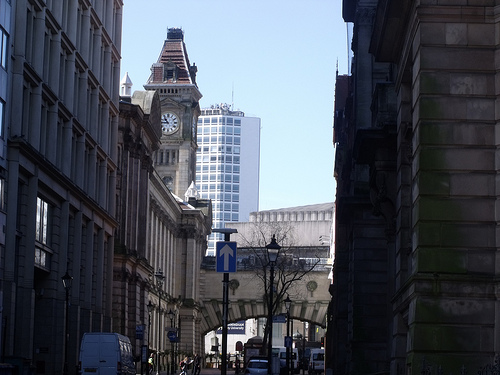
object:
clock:
[157, 109, 182, 134]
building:
[124, 15, 244, 245]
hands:
[162, 116, 179, 134]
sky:
[120, 0, 346, 212]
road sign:
[218, 240, 235, 272]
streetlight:
[194, 229, 319, 369]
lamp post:
[263, 232, 284, 370]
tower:
[126, 21, 200, 366]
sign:
[214, 235, 239, 277]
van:
[80, 330, 145, 373]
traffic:
[275, 348, 325, 371]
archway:
[226, 314, 325, 372]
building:
[188, 103, 263, 258]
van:
[284, 329, 297, 365]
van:
[308, 345, 328, 370]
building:
[240, 204, 335, 245]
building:
[322, 0, 499, 374]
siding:
[402, 22, 499, 373]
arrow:
[219, 244, 233, 271]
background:
[216, 241, 236, 271]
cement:
[203, 256, 329, 372]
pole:
[215, 243, 234, 368]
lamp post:
[163, 306, 184, 374]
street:
[117, 342, 330, 372]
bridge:
[198, 267, 333, 328]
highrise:
[194, 110, 263, 248]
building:
[17, 5, 143, 351]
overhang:
[211, 230, 334, 336]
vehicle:
[217, 329, 276, 372]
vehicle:
[281, 338, 316, 372]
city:
[0, 1, 499, 371]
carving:
[183, 245, 299, 341]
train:
[191, 216, 326, 272]